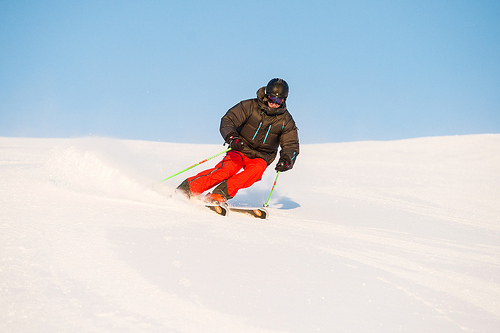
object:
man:
[175, 77, 302, 206]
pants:
[176, 150, 270, 200]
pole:
[155, 147, 235, 184]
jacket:
[218, 86, 301, 167]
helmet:
[264, 78, 290, 105]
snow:
[1, 133, 499, 332]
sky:
[1, 1, 497, 143]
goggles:
[265, 93, 287, 105]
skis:
[202, 204, 268, 222]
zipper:
[262, 123, 271, 147]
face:
[267, 92, 283, 113]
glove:
[230, 135, 246, 153]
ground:
[2, 134, 499, 332]